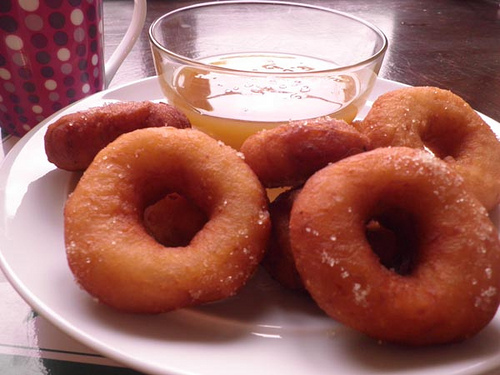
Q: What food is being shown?
A: Donuts.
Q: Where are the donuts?
A: On a plate.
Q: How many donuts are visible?
A: Five.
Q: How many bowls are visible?
A: One.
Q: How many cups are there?
A: One.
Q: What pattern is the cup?
A: Polka dot.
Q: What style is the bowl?
A: Transparent.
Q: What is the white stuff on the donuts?
A: Sugar.